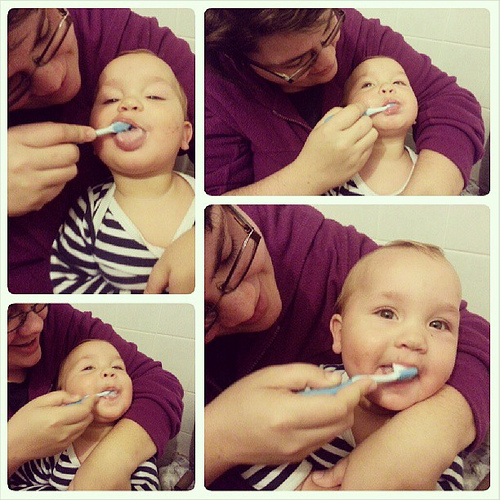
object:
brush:
[294, 363, 417, 397]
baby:
[231, 238, 463, 492]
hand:
[215, 362, 377, 465]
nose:
[391, 314, 428, 355]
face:
[63, 341, 132, 419]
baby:
[7, 337, 161, 492]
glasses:
[6, 8, 74, 108]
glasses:
[203, 204, 262, 336]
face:
[338, 258, 460, 411]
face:
[344, 57, 416, 131]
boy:
[320, 56, 418, 197]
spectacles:
[237, 8, 348, 86]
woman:
[204, 8, 486, 197]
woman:
[5, 10, 197, 294]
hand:
[7, 122, 96, 219]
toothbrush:
[91, 120, 130, 137]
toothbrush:
[320, 102, 397, 125]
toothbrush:
[63, 390, 110, 406]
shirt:
[46, 169, 196, 294]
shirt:
[321, 144, 419, 196]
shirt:
[14, 440, 162, 491]